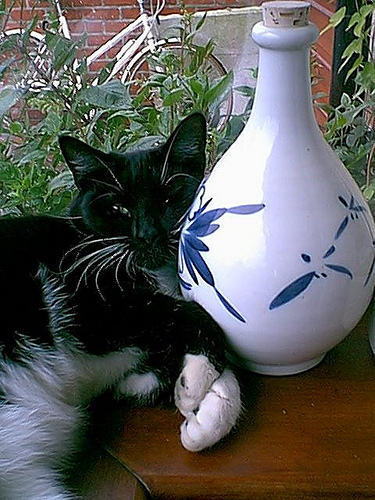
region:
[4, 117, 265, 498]
a black and white cat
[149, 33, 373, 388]
a blue and white vase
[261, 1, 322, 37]
a cork in the top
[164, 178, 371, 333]
blue design on white vase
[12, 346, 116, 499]
a white belly of cat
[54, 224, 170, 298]
white whiskers on the cat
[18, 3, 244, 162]
a white bike against wall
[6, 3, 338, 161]
a red brick wall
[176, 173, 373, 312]
blue floral design on vase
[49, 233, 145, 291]
long white whiskers on cat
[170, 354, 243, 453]
cat has white paws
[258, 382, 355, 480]
dark brown wooden table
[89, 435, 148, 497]
seam on wooden surface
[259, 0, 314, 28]
cork in top of bottle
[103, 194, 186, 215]
cat's eyes are partially closed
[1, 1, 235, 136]
white bicycle in background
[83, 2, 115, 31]
brick wall seen thru window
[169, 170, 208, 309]
cat is leaning against vase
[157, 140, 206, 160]
Cat has black ear.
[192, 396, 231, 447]
Cat has white paw.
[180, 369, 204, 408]
Cat has white paw.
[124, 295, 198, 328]
Cat has black leg.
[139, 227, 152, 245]
Cat has black nose.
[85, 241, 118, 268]
Cat has white whiskers.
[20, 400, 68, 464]
Cat has white tummy.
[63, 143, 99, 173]
Cat has black ear.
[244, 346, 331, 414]
White vase sitting on brown table.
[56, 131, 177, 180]
cat has black ears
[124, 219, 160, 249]
cat has black nose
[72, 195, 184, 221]
cat has green eyes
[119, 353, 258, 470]
cat has white paws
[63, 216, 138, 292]
cat has long white whiskers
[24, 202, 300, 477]
cat lying on brown table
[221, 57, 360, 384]
blue and white vase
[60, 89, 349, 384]
vase is next to cat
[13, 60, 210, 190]
green plants behind cat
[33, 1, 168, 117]
red brick wall outside window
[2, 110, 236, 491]
this is a cat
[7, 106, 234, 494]
this is a black and white cat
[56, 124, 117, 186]
this is a cat's ear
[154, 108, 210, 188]
this is a cat's ear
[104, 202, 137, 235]
this is a cat's eye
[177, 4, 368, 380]
this is a flower vase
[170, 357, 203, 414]
this is a cat's claw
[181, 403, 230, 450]
this is a cat's claw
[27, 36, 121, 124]
these are green leaves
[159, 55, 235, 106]
these are green leaves